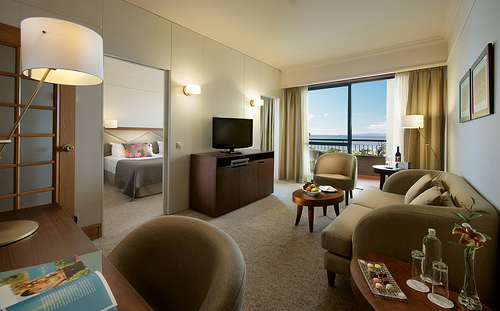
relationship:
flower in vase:
[454, 220, 490, 245] [460, 245, 485, 307]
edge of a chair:
[214, 255, 250, 309] [108, 212, 246, 307]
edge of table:
[43, 203, 71, 224] [0, 205, 158, 310]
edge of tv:
[211, 119, 219, 126] [211, 117, 254, 152]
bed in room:
[103, 136, 163, 199] [102, 57, 169, 227]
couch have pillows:
[321, 166, 498, 288] [403, 173, 457, 209]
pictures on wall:
[457, 44, 493, 123] [446, 1, 498, 205]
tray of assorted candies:
[357, 256, 408, 301] [365, 262, 396, 295]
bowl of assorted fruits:
[303, 187, 321, 196] [303, 181, 321, 191]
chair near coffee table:
[312, 149, 359, 205] [291, 184, 343, 232]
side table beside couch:
[373, 163, 407, 188] [321, 166, 498, 288]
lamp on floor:
[403, 113, 425, 179] [95, 178, 373, 307]